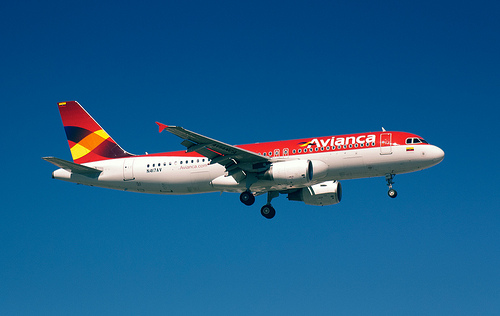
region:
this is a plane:
[42, 106, 452, 199]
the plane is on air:
[30, 100, 461, 220]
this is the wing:
[158, 120, 254, 162]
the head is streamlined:
[425, 142, 445, 167]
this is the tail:
[55, 95, 118, 150]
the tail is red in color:
[63, 108, 88, 120]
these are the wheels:
[241, 191, 279, 216]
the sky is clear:
[325, 215, 469, 307]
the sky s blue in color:
[241, 3, 416, 101]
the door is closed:
[377, 130, 394, 152]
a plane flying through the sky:
[33, 92, 452, 232]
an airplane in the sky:
[46, 80, 466, 238]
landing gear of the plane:
[224, 180, 428, 225]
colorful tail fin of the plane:
[37, 100, 124, 157]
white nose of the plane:
[402, 138, 447, 180]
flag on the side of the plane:
[402, 145, 417, 156]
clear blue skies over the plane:
[114, 229, 319, 293]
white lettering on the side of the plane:
[303, 138, 377, 145]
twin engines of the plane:
[216, 155, 356, 213]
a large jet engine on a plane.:
[287, 180, 359, 216]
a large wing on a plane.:
[53, 86, 140, 165]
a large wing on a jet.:
[146, 119, 275, 186]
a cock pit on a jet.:
[386, 113, 451, 175]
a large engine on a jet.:
[44, 160, 101, 195]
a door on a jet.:
[118, 154, 140, 199]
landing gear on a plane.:
[236, 180, 287, 225]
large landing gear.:
[380, 162, 415, 202]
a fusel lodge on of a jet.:
[49, 117, 444, 251]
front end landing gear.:
[372, 168, 412, 208]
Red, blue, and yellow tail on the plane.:
[55, 95, 121, 163]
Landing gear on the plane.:
[230, 185, 277, 220]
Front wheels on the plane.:
[380, 171, 395, 196]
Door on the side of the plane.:
[375, 130, 391, 155]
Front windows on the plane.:
[401, 131, 426, 141]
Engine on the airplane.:
[205, 160, 310, 195]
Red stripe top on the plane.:
[100, 130, 425, 155]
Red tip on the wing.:
[150, 116, 166, 131]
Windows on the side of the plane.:
[140, 156, 212, 166]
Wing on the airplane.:
[155, 115, 265, 181]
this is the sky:
[268, 19, 446, 108]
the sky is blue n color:
[261, 23, 378, 82]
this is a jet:
[52, 102, 419, 219]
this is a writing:
[303, 134, 380, 149]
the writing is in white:
[296, 135, 375, 146]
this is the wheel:
[259, 200, 284, 223]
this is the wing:
[157, 119, 257, 181]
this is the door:
[381, 129, 393, 156]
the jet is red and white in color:
[281, 138, 303, 159]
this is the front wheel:
[382, 186, 405, 204]